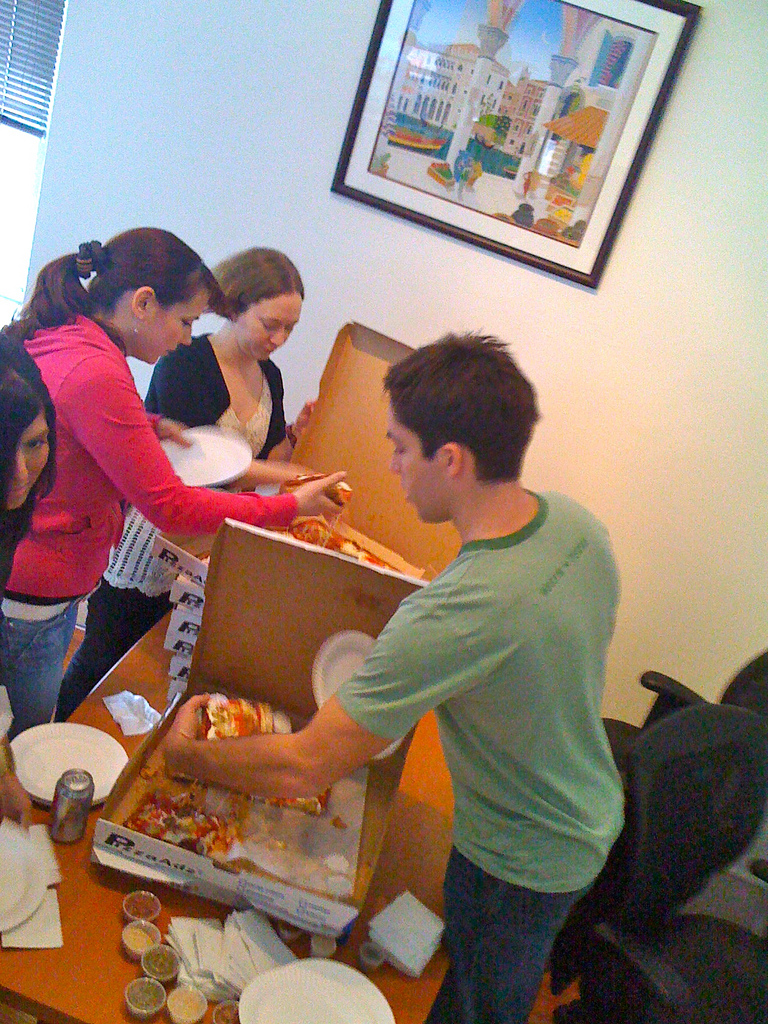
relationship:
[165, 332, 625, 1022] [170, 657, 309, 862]
boy picking up pizza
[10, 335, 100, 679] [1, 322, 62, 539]
woman with hair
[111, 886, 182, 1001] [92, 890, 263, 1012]
sauce in containers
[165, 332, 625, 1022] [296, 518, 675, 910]
boy in shirt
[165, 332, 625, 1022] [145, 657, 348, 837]
boy grabbing pizza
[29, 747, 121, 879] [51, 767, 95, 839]
can of can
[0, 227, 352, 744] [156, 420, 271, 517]
girl holding plate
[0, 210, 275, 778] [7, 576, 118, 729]
girl in jeans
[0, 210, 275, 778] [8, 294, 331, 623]
girl in sweatshirt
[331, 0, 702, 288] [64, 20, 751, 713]
art on wall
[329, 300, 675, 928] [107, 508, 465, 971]
boy digging into box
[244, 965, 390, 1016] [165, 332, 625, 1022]
paper plates by boy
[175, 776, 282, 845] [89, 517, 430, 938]
pieces left in box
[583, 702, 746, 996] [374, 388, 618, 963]
office chair behind man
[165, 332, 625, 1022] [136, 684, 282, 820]
boy getting pizza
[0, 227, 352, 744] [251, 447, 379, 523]
girl putting pizza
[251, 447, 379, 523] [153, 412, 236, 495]
pizza on a plate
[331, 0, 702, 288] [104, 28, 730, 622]
art on a wall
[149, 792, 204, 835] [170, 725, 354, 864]
slice of pizza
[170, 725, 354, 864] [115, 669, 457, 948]
pizza in box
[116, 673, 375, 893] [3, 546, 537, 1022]
pizza on table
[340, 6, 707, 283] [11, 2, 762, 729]
art on wall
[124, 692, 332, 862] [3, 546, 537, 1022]
pizza on table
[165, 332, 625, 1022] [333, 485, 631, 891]
boy in shirt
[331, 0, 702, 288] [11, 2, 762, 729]
art on wall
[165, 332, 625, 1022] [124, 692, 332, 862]
boy getting pizza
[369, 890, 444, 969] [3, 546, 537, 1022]
napkin on table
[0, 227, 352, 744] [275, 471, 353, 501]
girl picking up pizza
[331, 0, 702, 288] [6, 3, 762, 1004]
art on wall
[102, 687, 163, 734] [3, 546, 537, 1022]
napkin on table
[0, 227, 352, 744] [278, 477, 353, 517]
girl holding pizza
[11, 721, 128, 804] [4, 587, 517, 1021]
plate on table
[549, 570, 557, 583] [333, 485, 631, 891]
letter on shirt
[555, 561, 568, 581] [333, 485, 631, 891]
letter on shirt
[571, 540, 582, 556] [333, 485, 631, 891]
letter on shirt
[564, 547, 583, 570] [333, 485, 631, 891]
letter on shirt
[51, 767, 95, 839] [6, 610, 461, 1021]
can on table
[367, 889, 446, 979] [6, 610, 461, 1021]
napkin stacked on table